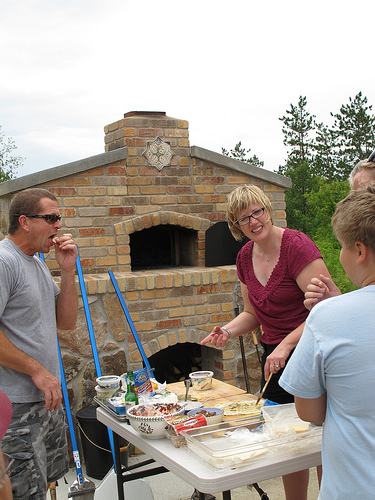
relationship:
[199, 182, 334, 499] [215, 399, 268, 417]
woman preparing pizza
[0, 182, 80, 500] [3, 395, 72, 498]
man wearing cargo pants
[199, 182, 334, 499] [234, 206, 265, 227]
woman wearing glasses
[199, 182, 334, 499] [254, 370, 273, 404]
woman holding brush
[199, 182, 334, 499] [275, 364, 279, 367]
woman wearing wedding ring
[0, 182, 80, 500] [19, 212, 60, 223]
man wearing black sunglasses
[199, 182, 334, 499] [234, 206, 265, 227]
woman wearing eyeglasses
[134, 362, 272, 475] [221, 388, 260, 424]
table full of food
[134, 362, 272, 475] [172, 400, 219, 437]
table full of food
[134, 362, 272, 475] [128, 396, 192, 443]
table full of food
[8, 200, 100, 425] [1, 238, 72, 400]
man wearing shirt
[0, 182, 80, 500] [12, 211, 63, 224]
man wearing sunglasses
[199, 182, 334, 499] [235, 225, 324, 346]
woman wearing blouse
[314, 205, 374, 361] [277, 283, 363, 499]
boy wearing shirt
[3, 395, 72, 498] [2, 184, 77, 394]
cargo pants on man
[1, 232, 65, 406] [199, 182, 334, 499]
shirt on woman